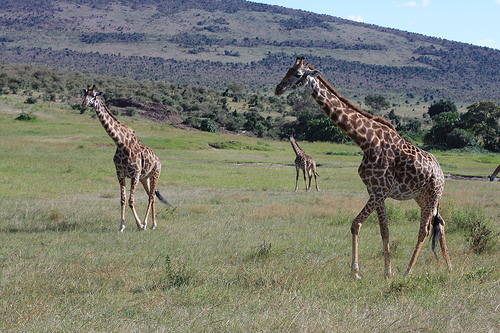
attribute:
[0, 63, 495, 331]
plain — green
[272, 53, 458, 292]
giraffe — brown, white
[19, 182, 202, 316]
plain — green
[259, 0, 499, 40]
sky — clear, blue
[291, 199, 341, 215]
grass — green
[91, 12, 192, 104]
bushes — green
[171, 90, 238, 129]
bushes — green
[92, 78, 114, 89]
bushes — green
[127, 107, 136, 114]
bushes — green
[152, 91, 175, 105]
bushes — green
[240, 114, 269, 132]
bushes — green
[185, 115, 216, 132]
bushes — green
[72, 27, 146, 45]
bushes — green